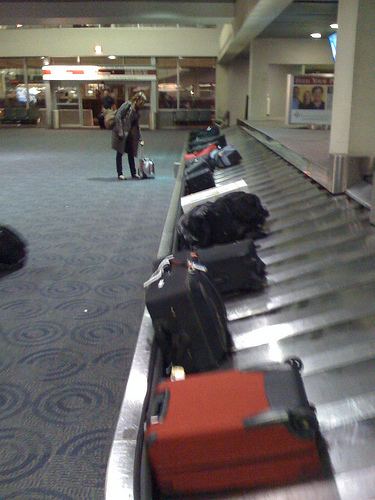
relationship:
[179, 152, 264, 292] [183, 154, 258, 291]
bags in a row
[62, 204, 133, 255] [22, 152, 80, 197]
carpet on top of floor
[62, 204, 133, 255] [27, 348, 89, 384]
carpet has circular design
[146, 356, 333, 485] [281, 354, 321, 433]
bag has wheels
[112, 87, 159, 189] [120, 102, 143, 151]
woman wearing coat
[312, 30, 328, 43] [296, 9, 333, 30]
light in ceiling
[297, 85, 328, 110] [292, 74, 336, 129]
people are on advertisement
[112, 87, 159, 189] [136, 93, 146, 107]
woman has hair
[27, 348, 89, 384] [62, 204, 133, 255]
circular design on carpet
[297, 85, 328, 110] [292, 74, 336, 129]
image on sign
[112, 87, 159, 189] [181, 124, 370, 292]
woman next to baggage carousel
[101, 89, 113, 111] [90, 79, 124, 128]
man in entryway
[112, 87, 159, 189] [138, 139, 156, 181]
woman gripping on to luggage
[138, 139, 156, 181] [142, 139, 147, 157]
luggage has handle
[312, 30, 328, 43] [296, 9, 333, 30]
light on ceiling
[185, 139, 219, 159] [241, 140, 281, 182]
luggage on top of belt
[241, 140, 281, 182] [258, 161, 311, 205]
belt made of metal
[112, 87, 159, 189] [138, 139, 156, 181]
woman picking up luggage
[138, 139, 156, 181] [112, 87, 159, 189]
luggage belongs to woman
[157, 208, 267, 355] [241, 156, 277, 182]
three suitcases on top of belt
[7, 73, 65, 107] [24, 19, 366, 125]
shops inside of airport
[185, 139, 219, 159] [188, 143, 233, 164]
luggage in distance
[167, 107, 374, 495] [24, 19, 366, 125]
baggage claim inside of airport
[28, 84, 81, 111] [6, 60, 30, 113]
restaurant has huge windows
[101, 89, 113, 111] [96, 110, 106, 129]
man carrying luggage